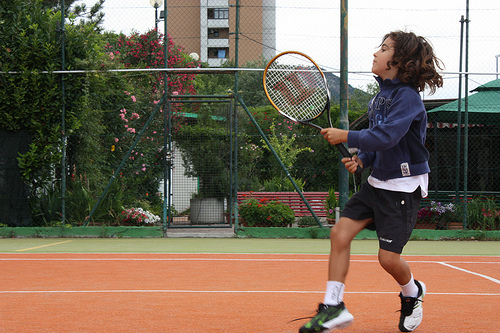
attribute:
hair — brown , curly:
[397, 22, 456, 116]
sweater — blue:
[348, 94, 452, 188]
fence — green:
[57, 185, 404, 271]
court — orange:
[38, 143, 468, 331]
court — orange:
[26, 168, 463, 319]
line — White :
[45, 252, 385, 304]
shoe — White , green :
[283, 268, 461, 330]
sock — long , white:
[316, 270, 348, 315]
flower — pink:
[111, 96, 170, 167]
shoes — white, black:
[292, 277, 428, 329]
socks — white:
[315, 270, 417, 303]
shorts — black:
[338, 155, 428, 258]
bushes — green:
[9, 5, 368, 233]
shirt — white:
[357, 164, 430, 199]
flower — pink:
[109, 85, 149, 146]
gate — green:
[164, 95, 236, 241]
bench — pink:
[235, 187, 335, 224]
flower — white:
[130, 205, 158, 222]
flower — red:
[112, 208, 145, 225]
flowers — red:
[244, 193, 279, 221]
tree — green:
[64, 34, 171, 222]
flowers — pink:
[103, 84, 178, 193]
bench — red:
[238, 187, 343, 224]